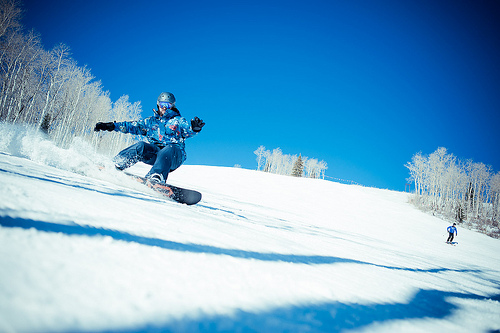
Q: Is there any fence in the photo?
A: No, there are no fences.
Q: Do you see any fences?
A: No, there are no fences.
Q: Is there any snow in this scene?
A: Yes, there is snow.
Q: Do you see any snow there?
A: Yes, there is snow.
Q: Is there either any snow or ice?
A: Yes, there is snow.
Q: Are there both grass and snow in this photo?
A: No, there is snow but no grass.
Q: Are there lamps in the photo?
A: No, there are no lamps.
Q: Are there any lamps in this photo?
A: No, there are no lamps.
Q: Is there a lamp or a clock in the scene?
A: No, there are no lamps or clocks.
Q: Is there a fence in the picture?
A: No, there are no fences.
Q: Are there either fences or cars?
A: No, there are no fences or cars.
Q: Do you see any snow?
A: Yes, there is snow.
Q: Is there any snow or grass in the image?
A: Yes, there is snow.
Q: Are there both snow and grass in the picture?
A: No, there is snow but no grass.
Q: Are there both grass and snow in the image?
A: No, there is snow but no grass.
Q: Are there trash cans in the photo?
A: No, there are no trash cans.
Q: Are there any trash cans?
A: No, there are no trash cans.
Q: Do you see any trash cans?
A: No, there are no trash cans.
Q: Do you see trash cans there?
A: No, there are no trash cans.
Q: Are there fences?
A: No, there are no fences.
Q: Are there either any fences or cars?
A: No, there are no fences or cars.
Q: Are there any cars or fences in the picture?
A: No, there are no fences or cars.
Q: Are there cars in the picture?
A: No, there are no cars.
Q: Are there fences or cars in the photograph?
A: No, there are no cars or fences.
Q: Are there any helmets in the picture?
A: Yes, there is a helmet.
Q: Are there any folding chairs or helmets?
A: Yes, there is a helmet.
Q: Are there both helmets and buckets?
A: No, there is a helmet but no buckets.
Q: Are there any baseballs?
A: No, there are no baseballs.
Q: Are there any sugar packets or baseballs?
A: No, there are no baseballs or sugar packets.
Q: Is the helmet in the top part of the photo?
A: Yes, the helmet is in the top of the image.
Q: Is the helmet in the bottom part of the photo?
A: No, the helmet is in the top of the image.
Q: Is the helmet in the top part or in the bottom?
A: The helmet is in the top of the image.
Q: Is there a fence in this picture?
A: No, there are no fences.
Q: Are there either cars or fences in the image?
A: No, there are no fences or cars.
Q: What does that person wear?
A: The person wears a helmet.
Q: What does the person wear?
A: The person wears a helmet.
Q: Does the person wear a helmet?
A: Yes, the person wears a helmet.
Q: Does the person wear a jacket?
A: No, the person wears a helmet.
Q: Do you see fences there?
A: No, there are no fences.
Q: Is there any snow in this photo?
A: Yes, there is snow.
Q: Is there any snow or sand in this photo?
A: Yes, there is snow.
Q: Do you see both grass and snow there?
A: No, there is snow but no grass.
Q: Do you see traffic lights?
A: No, there are no traffic lights.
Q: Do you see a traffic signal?
A: No, there are no traffic lights.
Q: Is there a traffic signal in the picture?
A: No, there are no traffic lights.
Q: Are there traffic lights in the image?
A: No, there are no traffic lights.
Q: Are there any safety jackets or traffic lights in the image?
A: No, there are no traffic lights or safety jackets.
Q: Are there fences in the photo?
A: No, there are no fences.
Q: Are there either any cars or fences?
A: No, there are no fences or cars.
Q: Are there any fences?
A: No, there are no fences.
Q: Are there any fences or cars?
A: No, there are no fences or cars.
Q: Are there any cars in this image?
A: No, there are no cars.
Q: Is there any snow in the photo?
A: Yes, there is snow.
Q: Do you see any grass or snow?
A: Yes, there is snow.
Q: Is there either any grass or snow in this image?
A: Yes, there is snow.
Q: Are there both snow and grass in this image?
A: No, there is snow but no grass.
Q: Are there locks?
A: No, there are no locks.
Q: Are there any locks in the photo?
A: No, there are no locks.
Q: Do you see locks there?
A: No, there are no locks.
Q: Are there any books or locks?
A: No, there are no locks or books.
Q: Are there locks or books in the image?
A: No, there are no locks or books.